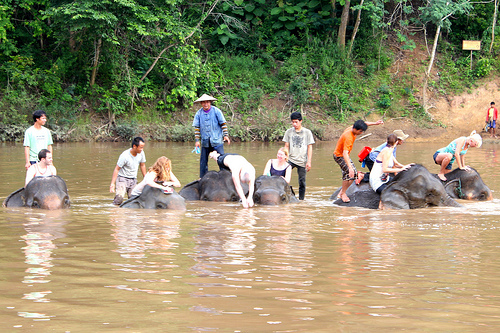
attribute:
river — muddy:
[6, 141, 498, 331]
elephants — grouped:
[136, 157, 470, 204]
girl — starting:
[438, 131, 483, 172]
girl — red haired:
[125, 152, 187, 202]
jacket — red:
[478, 102, 498, 123]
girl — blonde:
[433, 131, 481, 180]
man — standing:
[485, 101, 496, 136]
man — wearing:
[183, 87, 240, 180]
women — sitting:
[262, 143, 297, 179]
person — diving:
[215, 147, 265, 211]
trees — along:
[11, 2, 405, 110]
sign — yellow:
[459, 36, 480, 53]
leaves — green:
[70, 8, 119, 40]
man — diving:
[206, 148, 258, 207]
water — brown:
[3, 142, 497, 332]